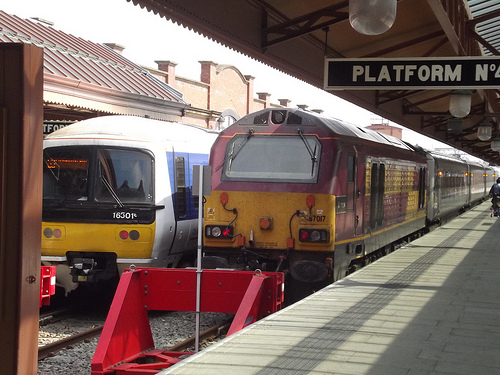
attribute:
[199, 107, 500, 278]
train — during day, sitting still, parked, burgundy, yellow, red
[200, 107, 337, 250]
end — yellow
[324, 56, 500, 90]
sign — white, black, hanging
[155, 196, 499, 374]
walkway — concrete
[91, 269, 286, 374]
blockade — triangular, red, metal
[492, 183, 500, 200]
back — showing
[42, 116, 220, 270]
train — parked, silver, during day, sitting still, gray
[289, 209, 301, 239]
cord — black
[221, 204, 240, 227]
cord — black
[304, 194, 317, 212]
light — orange, round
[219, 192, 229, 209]
light — orange, round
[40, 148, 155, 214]
windshield — black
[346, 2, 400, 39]
light — overhead, tubular, white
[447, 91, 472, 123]
light — overhead, tubular, white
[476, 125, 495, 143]
light — overhead, tubular, white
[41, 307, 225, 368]
gravel — gray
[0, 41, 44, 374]
bearn — wooden, brown